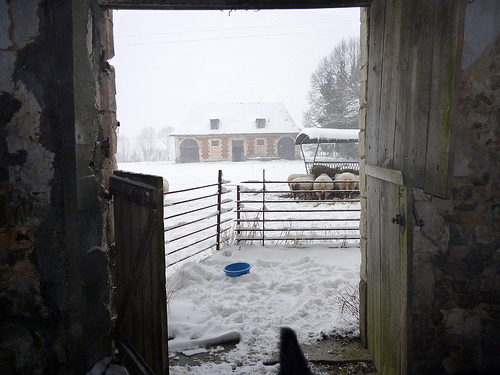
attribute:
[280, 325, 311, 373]
stone — part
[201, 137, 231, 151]
window — glass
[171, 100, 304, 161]
house — brick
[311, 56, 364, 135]
tree — large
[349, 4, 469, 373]
door — open, wood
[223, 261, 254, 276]
bucket — blue, plastic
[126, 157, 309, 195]
ground — snow covered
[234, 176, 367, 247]
fence — metal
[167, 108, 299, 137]
roof — snow covered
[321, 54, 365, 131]
tree — leafless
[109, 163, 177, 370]
door — halved, wood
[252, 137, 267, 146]
window — glass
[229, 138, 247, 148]
window — glass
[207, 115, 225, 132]
window — glass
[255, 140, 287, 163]
window — glass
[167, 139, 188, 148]
window — glass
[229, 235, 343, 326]
snow — white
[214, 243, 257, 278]
bowl — blue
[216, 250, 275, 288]
bowl — blue